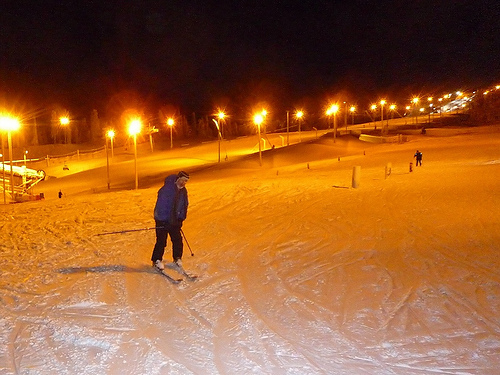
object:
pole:
[134, 140, 140, 191]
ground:
[0, 129, 499, 375]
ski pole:
[90, 226, 166, 238]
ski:
[175, 261, 199, 281]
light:
[125, 119, 141, 135]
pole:
[180, 229, 194, 257]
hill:
[0, 125, 499, 373]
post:
[350, 165, 361, 189]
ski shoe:
[172, 256, 184, 268]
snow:
[0, 116, 499, 374]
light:
[326, 102, 340, 115]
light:
[294, 110, 304, 118]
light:
[251, 111, 267, 127]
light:
[165, 116, 175, 128]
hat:
[173, 170, 188, 182]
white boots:
[152, 261, 169, 272]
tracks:
[237, 263, 294, 344]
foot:
[153, 256, 165, 267]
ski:
[157, 272, 183, 285]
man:
[149, 169, 190, 272]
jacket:
[153, 175, 189, 230]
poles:
[256, 127, 263, 167]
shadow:
[55, 265, 157, 277]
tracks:
[125, 257, 222, 375]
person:
[411, 150, 423, 168]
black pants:
[150, 225, 182, 263]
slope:
[0, 126, 498, 374]